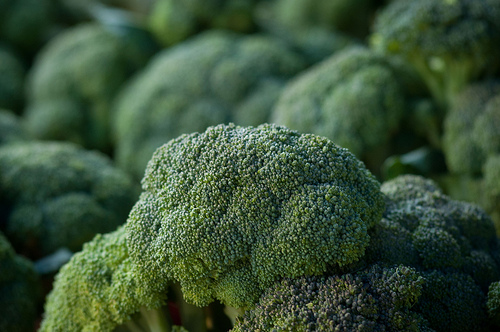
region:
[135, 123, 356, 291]
A head of green broccoli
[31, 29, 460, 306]
A bunch of broccoli together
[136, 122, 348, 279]
A large piece of broccoli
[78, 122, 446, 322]
A group of broccoli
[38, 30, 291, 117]
Green broccoli in the background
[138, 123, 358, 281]
A large head of broccoli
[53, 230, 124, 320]
A head of broccoli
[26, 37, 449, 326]
A group of large broccoli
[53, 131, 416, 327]
Well maintained group of broccoli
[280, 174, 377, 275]
top of broccoli stem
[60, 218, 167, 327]
top of broccoli stem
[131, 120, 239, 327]
top of broccoli stem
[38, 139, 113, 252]
top of broccoli stem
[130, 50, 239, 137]
top of broccoli stem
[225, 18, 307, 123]
top of broccoli stem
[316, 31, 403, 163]
top of broccoli stem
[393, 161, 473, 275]
top of broccoli stem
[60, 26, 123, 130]
top of broccoli stem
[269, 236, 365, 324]
top of broccoli stem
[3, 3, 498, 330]
a close up of brocolli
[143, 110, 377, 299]
it puts one in mind of brain coral...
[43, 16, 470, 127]
the background is all brocolli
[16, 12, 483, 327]
that's a lot of green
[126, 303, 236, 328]
the stalks of brocolli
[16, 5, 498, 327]
it looks like a green forest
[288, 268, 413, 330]
this part of the brocolli looks purple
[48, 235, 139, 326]
this section is a lighter shade of green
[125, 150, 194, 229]
this is a piece of vegetable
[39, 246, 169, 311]
this is a piece of vegetable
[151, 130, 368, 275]
this is a piece of vegetable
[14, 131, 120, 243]
this is a piece of vegetable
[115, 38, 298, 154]
this is a piece of vegetable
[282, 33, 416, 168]
this is a piece of vegetable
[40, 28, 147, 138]
this is a piece of vegetable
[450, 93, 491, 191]
this is a piece of vegetable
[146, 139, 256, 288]
this is a piece of vegetable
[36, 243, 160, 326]
this is a piece of vegetable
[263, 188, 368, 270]
this is a piece of vegetable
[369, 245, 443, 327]
this is a piece of vegetable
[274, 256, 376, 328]
this is a piece of vegetable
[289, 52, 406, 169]
this is a piece of vegetable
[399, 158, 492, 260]
this is a piece of vegetable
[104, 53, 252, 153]
this is a piece of vegetable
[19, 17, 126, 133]
this is a piece of vegetable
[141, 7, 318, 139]
this is a piece of vegetable